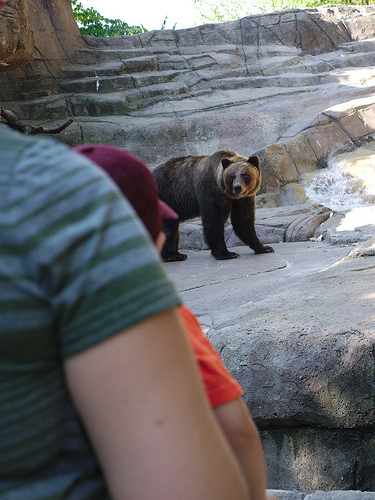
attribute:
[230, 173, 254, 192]
nose — black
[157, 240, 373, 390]
ground — gray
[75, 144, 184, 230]
cap — maroon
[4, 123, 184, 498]
shirt — gray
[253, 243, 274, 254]
paw — black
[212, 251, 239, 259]
paw — black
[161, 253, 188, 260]
paw — black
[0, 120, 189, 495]
t shirt — green , Blue 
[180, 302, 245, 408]
shirt — orange 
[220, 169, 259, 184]
eyes — dark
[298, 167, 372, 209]
water — running, rapid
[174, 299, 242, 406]
shirt — Orange 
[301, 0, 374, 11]
leaves — green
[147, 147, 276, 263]
bear — brown, black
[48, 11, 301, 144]
rocks — brown 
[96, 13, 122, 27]
leaves — green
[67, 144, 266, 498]
shirt — orange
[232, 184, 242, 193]
nose — brown  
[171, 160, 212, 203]
fur — brown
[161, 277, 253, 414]
shirt — orange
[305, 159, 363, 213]
foam — white